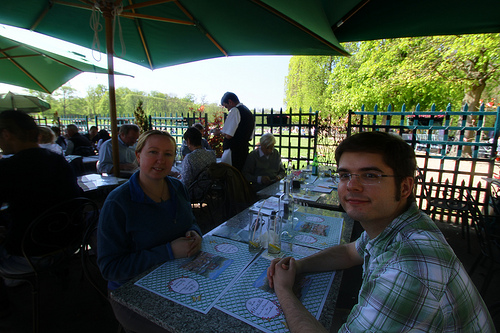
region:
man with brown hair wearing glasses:
[330, 128, 428, 234]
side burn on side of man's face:
[373, 159, 410, 209]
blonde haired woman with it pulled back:
[130, 126, 181, 191]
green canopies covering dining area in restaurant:
[2, 2, 495, 176]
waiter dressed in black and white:
[199, 89, 259, 190]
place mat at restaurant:
[128, 230, 270, 317]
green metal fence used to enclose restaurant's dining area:
[5, 94, 499, 231]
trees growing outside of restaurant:
[11, 32, 498, 164]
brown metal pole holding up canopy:
[100, 0, 127, 190]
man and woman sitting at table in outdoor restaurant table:
[87, 120, 498, 331]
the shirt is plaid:
[395, 253, 431, 283]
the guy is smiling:
[338, 191, 375, 210]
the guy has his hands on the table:
[267, 248, 306, 299]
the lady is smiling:
[147, 161, 168, 176]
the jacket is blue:
[113, 208, 148, 238]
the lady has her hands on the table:
[167, 226, 211, 260]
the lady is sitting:
[83, 268, 118, 302]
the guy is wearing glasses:
[333, 161, 386, 195]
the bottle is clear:
[277, 191, 294, 229]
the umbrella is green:
[156, 46, 182, 63]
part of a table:
[193, 296, 209, 326]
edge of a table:
[156, 260, 158, 277]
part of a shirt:
[408, 263, 420, 278]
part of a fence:
[454, 148, 481, 182]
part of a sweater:
[147, 210, 155, 221]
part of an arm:
[348, 218, 353, 244]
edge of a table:
[138, 291, 146, 302]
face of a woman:
[151, 162, 159, 179]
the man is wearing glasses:
[333, 166, 382, 188]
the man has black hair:
[343, 128, 399, 160]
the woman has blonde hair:
[138, 123, 175, 147]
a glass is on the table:
[264, 223, 283, 252]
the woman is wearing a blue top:
[106, 189, 198, 256]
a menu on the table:
[148, 230, 246, 304]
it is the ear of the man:
[400, 176, 413, 203]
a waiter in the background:
[221, 89, 253, 154]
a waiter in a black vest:
[231, 106, 248, 143]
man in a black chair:
[7, 151, 77, 244]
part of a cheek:
[392, 186, 402, 201]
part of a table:
[213, 157, 225, 314]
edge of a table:
[155, 287, 177, 314]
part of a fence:
[288, 124, 297, 167]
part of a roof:
[211, 33, 222, 63]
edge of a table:
[161, 299, 181, 323]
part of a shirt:
[414, 280, 426, 296]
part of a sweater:
[120, 223, 130, 236]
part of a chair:
[51, 250, 70, 270]